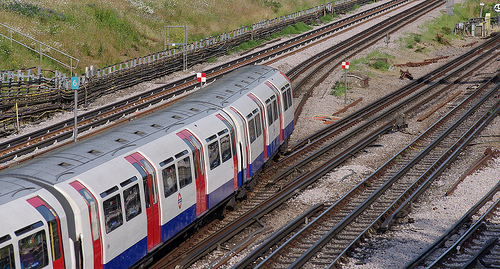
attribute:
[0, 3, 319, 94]
grassy area —  grassy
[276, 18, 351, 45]
tracks — metal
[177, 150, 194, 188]
window — square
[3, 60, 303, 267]
train car —  train's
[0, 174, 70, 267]
train car —  train's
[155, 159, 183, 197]
window — square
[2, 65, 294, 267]
train — silver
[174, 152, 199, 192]
window — square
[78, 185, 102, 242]
window — Long 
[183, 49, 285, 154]
car —  train's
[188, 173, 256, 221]
stripe — blue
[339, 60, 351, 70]
sign — red, white, checkered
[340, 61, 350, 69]
sign —  red and white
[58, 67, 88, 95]
sign — green, white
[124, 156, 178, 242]
door — red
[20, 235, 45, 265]
window —  square